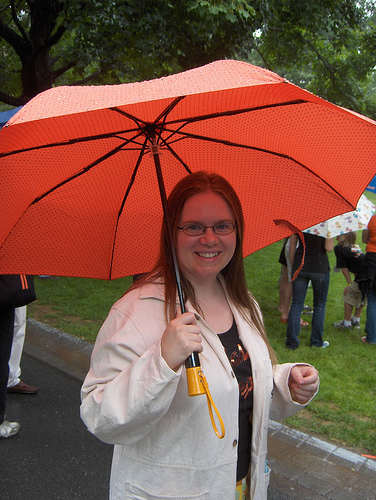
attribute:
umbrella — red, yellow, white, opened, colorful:
[2, 28, 363, 279]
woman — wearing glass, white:
[79, 143, 301, 500]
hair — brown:
[166, 174, 194, 213]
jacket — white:
[86, 260, 277, 482]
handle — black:
[173, 313, 217, 379]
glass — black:
[162, 184, 258, 246]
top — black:
[207, 327, 266, 443]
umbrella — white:
[311, 195, 362, 256]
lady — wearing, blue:
[287, 276, 339, 355]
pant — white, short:
[0, 298, 50, 399]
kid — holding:
[302, 231, 369, 365]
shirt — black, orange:
[216, 326, 252, 446]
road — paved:
[17, 349, 91, 481]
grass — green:
[60, 289, 92, 323]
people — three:
[249, 209, 374, 329]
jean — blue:
[240, 271, 332, 403]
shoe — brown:
[13, 378, 46, 403]